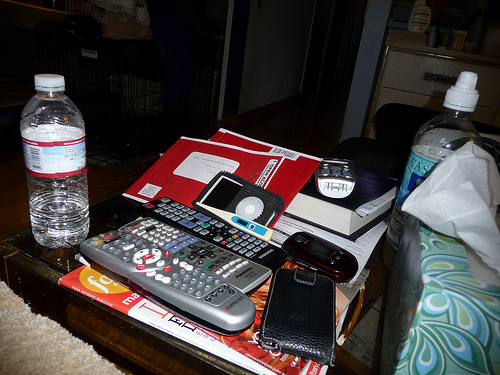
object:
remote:
[141, 193, 283, 270]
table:
[1, 133, 373, 375]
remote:
[115, 216, 269, 293]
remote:
[79, 233, 256, 334]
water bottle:
[22, 73, 92, 249]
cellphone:
[280, 231, 357, 281]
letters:
[123, 137, 277, 227]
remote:
[314, 157, 357, 199]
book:
[285, 162, 401, 236]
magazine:
[57, 254, 362, 374]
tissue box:
[376, 204, 498, 375]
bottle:
[380, 70, 482, 271]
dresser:
[360, 30, 499, 139]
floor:
[1, 83, 233, 244]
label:
[23, 133, 87, 177]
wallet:
[255, 267, 340, 366]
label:
[396, 150, 439, 203]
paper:
[356, 188, 399, 217]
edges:
[317, 178, 355, 199]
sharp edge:
[238, 265, 273, 295]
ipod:
[192, 171, 287, 228]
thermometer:
[194, 202, 274, 242]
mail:
[207, 127, 320, 228]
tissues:
[400, 132, 499, 268]